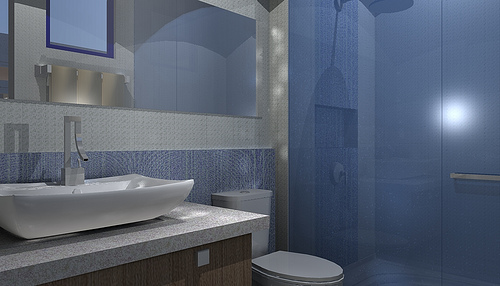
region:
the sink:
[17, 183, 149, 205]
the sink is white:
[25, 179, 146, 208]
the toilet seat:
[267, 246, 325, 278]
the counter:
[192, 210, 239, 232]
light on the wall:
[435, 83, 479, 128]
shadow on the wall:
[2, 117, 37, 152]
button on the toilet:
[232, 185, 256, 199]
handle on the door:
[446, 167, 498, 187]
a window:
[55, 9, 112, 48]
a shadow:
[313, 59, 350, 94]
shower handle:
[330, 160, 348, 187]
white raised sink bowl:
[0, 171, 195, 237]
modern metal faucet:
[61, 114, 88, 182]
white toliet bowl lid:
[250, 248, 344, 284]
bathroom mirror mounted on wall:
[0, 0, 255, 118]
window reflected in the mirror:
[45, 0, 113, 60]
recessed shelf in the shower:
[310, 101, 356, 146]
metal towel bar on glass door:
[445, 166, 495, 177]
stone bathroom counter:
[0, 200, 265, 285]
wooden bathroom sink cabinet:
[33, 233, 258, 285]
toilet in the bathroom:
[217, 180, 320, 279]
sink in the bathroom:
[33, 144, 183, 242]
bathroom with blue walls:
[333, 60, 482, 217]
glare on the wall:
[406, 88, 483, 160]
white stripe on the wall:
[141, 115, 267, 152]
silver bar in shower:
[441, 141, 488, 189]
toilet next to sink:
[224, 185, 332, 268]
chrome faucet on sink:
[41, 117, 108, 187]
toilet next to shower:
[208, 153, 377, 279]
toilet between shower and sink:
[220, 170, 343, 277]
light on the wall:
[425, 99, 482, 141]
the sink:
[8, 175, 173, 217]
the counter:
[180, 204, 228, 237]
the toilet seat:
[269, 255, 326, 277]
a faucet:
[60, 118, 102, 168]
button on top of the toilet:
[236, 185, 257, 197]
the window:
[49, 4, 111, 54]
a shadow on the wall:
[265, 25, 302, 107]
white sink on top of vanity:
[1, 171, 199, 238]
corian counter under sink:
[1, 200, 268, 285]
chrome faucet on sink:
[63, 115, 95, 183]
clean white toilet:
[214, 188, 345, 284]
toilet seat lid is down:
[251, 245, 342, 285]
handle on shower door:
[449, 172, 499, 188]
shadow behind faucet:
[3, 125, 35, 178]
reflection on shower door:
[431, 92, 471, 134]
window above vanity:
[49, 2, 114, 55]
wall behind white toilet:
[1, 1, 280, 251]